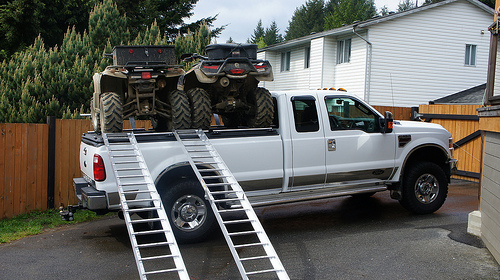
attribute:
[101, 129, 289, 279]
ramp ramp — white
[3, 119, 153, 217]
wooden fence — brown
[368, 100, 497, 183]
wooden fence — brown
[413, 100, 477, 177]
fence — beyond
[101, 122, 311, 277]
ramp — loading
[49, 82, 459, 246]
truck — white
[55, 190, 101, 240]
hitch — trailer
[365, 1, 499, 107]
wall — white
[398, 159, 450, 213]
tire —  truck's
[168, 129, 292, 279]
ramp — silver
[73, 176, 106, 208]
bumper — black, silver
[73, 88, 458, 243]
truck — white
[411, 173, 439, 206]
wheel — aluminum, alloy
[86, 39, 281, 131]
atvs —  Two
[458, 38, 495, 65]
window — slider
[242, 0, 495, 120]
building — white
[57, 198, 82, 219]
hitch —  trailer's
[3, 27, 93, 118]
trees —  pine